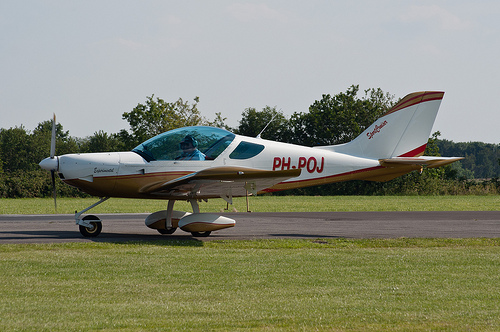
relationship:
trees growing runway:
[1, 85, 498, 197] [0, 210, 498, 242]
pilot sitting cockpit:
[175, 134, 207, 161] [135, 124, 227, 162]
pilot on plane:
[172, 123, 200, 162] [38, 90, 465, 239]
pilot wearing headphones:
[175, 134, 207, 161] [187, 135, 198, 147]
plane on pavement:
[38, 90, 465, 239] [0, 210, 499, 239]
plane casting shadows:
[38, 90, 465, 239] [0, 228, 205, 246]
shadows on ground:
[0, 228, 205, 246] [0, 197, 499, 330]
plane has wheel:
[38, 90, 465, 239] [77, 215, 102, 242]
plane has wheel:
[38, 90, 465, 239] [190, 229, 212, 238]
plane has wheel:
[38, 90, 465, 239] [158, 227, 177, 237]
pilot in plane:
[175, 134, 207, 161] [29, 90, 443, 232]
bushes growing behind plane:
[3, 118, 40, 190] [38, 90, 465, 239]